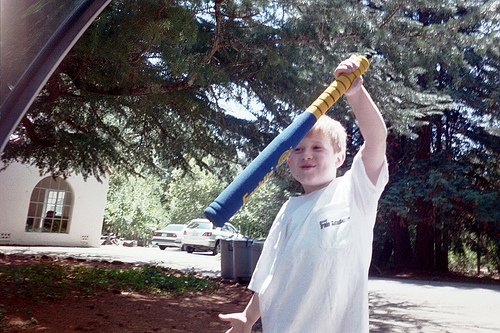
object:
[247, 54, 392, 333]
boy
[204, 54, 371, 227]
bat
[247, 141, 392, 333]
shirt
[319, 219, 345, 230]
letters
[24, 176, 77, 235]
window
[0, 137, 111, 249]
building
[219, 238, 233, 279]
trash can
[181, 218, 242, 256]
car